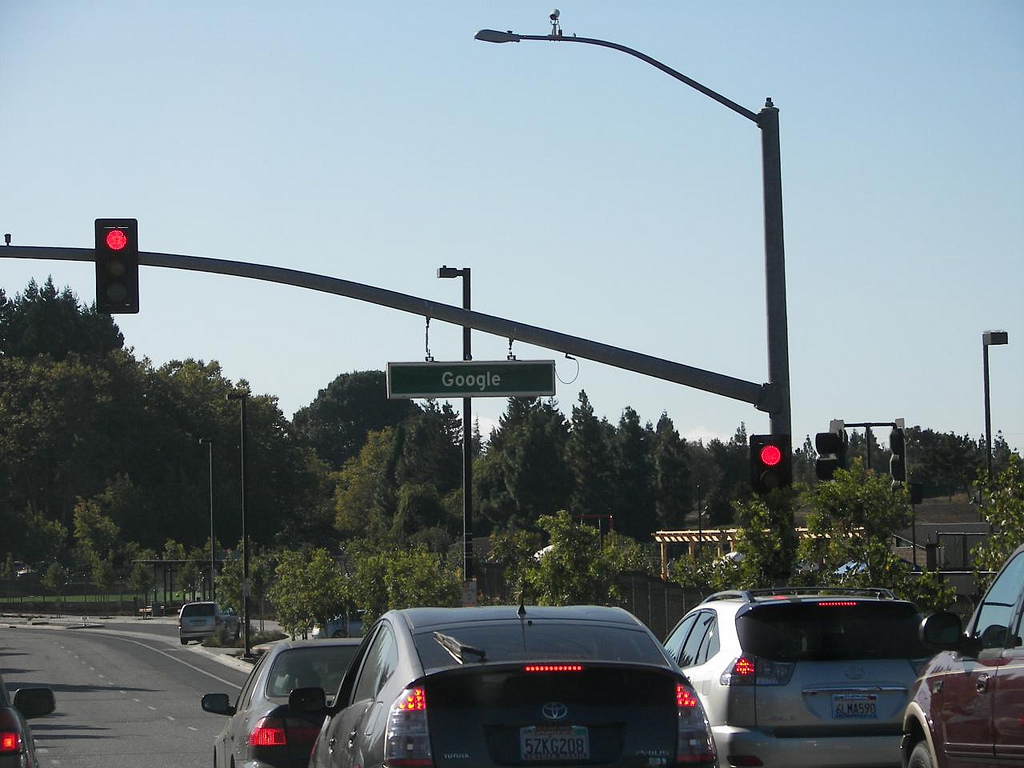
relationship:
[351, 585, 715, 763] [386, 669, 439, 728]
car has a light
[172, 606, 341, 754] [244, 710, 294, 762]
car has a light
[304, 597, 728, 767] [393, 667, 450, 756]
car has a light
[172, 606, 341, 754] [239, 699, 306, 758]
car has a light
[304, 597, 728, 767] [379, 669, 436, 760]
car has a light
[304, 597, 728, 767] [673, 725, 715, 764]
car has a light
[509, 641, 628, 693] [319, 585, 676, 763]
light on car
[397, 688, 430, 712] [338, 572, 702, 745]
light on car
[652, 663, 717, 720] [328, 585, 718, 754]
light on car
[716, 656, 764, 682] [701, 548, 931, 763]
light on car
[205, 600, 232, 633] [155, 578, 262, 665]
light on car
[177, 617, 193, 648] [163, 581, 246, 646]
light on car